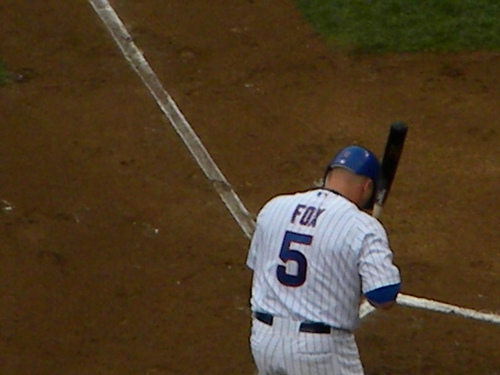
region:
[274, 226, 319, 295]
the large number 5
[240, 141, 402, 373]
the baseball player has a bat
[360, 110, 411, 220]
the bat is black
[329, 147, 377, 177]
the blue baseball helmet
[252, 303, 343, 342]
the player's black belt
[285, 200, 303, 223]
the letter F on the uniform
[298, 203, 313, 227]
the letter O on the uniform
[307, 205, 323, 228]
the letter X on the uniform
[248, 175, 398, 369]
the pin stripe uniform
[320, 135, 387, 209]
the head of the baseball player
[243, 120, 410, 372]
Baseball player wearing a white uniform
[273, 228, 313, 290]
Blue number five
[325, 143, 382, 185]
Blue baseball helmet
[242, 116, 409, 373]
Man holding a bat against his head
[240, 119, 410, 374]
Baseball player holding a bat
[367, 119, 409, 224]
Black and wood bat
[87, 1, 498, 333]
White chalk lines on a baseball diamond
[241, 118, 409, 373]
Man playing baseball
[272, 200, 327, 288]
Last name and number on the back of a shirt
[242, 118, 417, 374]
Man wearing a white pinstripe uniform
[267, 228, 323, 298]
player number on back of shirt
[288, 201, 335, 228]
player name on back of baseball shirt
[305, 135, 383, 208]
blue hard plastic safety helmet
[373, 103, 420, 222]
black metal baseball bat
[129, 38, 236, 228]
white strip painted on baseball field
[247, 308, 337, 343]
black belt on waist of baseball player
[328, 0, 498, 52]
green grass growing on baseball field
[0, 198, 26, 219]
small rock laying on baseball field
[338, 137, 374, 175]
light reflection on top of hard plastic safety helmet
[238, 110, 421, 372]
A professional baseball player out on the ball field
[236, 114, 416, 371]
A professional baseball player out on the ball field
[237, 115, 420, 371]
A professional baseball player out on the ball field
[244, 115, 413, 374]
a baseball player looking down at the ground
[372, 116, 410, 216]
a black baseball bat in the players hands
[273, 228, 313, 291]
the number 5 on the back of the player's uniform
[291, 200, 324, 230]
the name "Fox" on the back of the players uniform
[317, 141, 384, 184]
a blue helmet on the player's head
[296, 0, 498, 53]
a patch of grass on the baseball field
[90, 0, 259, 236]
a faded white stripe painted on the baseball field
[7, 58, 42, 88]
a foot print in the dirt on the baseball field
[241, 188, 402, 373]
a striped baseball uniform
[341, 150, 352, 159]
an emblem on the back of the baseball helmet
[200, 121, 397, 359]
a person is playing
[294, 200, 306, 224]
A letter on a jersey.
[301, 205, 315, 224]
A letter on a jersey.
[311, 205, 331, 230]
A letter on a jersey.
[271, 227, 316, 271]
A number on the jersey.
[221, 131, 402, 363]
A person is playing.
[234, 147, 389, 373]
A person is standing up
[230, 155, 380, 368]
A person is looking down.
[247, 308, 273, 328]
A black baseball belt.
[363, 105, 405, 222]
A bat.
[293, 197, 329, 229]
FOX written on the jersey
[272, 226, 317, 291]
5 on the back of the jersey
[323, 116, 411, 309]
batter holding a bat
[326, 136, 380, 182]
batting helmet is blue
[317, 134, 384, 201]
batter is wearing a batting helmet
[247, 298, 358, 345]
batter is wearing a belt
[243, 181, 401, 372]
uniform has stripes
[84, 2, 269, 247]
base line in the dirt